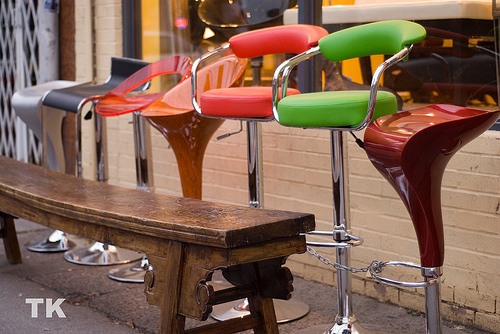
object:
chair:
[271, 18, 426, 131]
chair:
[190, 23, 328, 123]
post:
[325, 128, 358, 331]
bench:
[0, 154, 317, 333]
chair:
[87, 54, 190, 122]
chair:
[37, 56, 149, 117]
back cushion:
[316, 18, 428, 64]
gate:
[0, 0, 58, 163]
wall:
[78, 97, 500, 332]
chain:
[305, 244, 381, 278]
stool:
[360, 104, 498, 332]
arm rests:
[267, 39, 321, 124]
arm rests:
[356, 45, 409, 133]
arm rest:
[186, 42, 234, 119]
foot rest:
[368, 259, 434, 290]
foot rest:
[300, 228, 362, 248]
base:
[63, 239, 143, 268]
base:
[208, 295, 313, 327]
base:
[26, 231, 74, 255]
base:
[103, 257, 153, 285]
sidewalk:
[0, 216, 498, 334]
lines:
[10, 266, 150, 333]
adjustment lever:
[212, 121, 246, 142]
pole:
[420, 271, 445, 333]